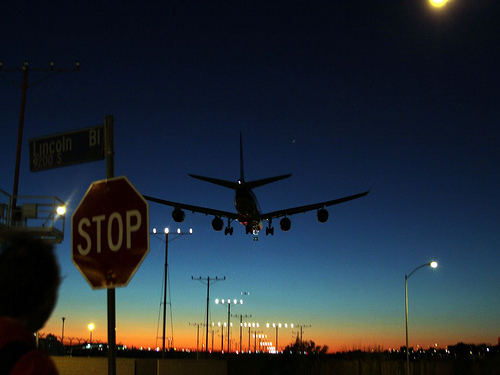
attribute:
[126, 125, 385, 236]
plane — departing, low, large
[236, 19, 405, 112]
night — approaching, black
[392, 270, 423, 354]
light pole — silver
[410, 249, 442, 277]
light — on, tall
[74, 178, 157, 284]
stop sign — red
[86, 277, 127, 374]
pole — metal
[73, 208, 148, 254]
lettering — white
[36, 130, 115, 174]
street sign — green, rectangular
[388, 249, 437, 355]
street light — tall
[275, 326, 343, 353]
trees — silhouetted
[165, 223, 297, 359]
street lights — aligned, in distance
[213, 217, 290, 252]
wheels — lowered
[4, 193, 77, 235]
platform — metal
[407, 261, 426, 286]
arm — metal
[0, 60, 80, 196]
pole — off, tall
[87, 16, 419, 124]
sky — clear, dark blue, blue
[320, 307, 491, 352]
sky — orange